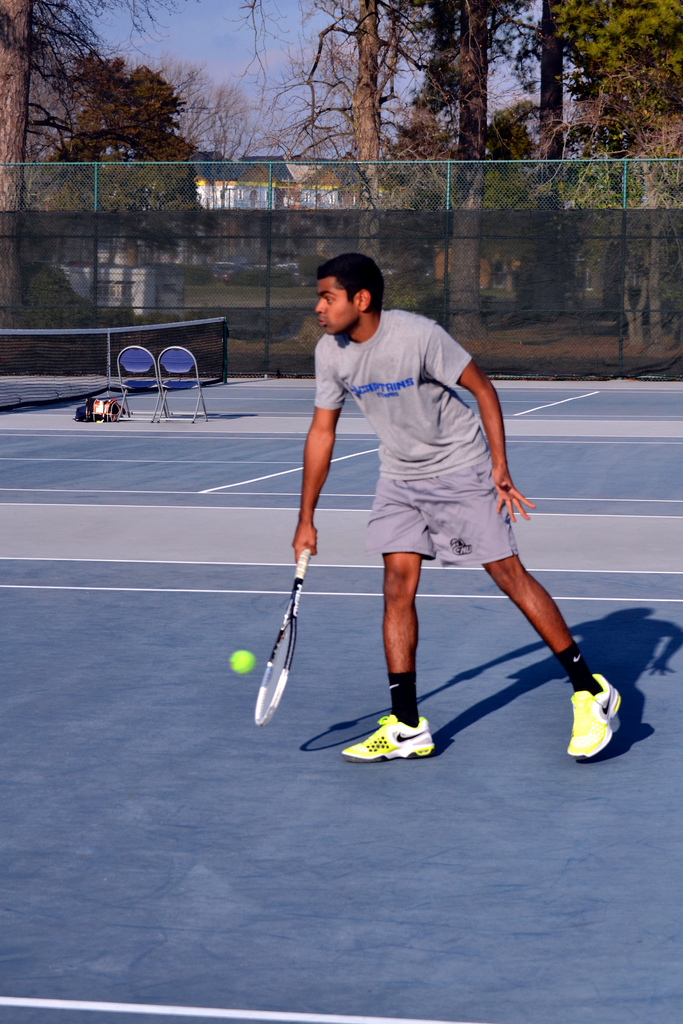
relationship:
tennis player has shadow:
[253, 253, 636, 778] [295, 591, 678, 756]